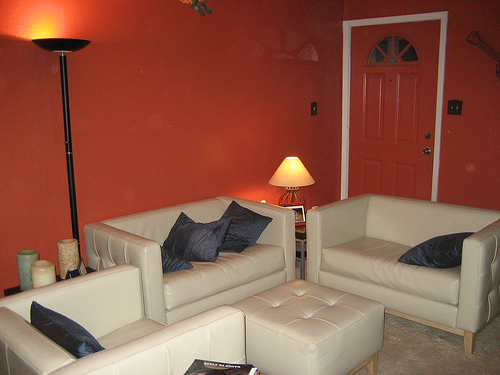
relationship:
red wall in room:
[0, 0, 499, 218] [9, 3, 497, 373]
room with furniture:
[9, 3, 497, 373] [10, 192, 499, 372]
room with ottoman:
[9, 3, 497, 373] [221, 266, 383, 371]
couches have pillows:
[2, 185, 487, 373] [147, 191, 284, 278]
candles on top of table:
[15, 234, 97, 286] [3, 265, 93, 301]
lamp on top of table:
[266, 155, 316, 207] [292, 207, 316, 273]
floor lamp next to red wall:
[33, 36, 92, 273] [0, 0, 499, 218]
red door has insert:
[345, 14, 442, 201] [358, 31, 423, 67]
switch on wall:
[444, 95, 468, 115] [347, 8, 497, 206]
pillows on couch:
[131, 180, 301, 289] [77, 192, 295, 329]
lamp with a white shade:
[266, 155, 316, 207] [269, 151, 319, 189]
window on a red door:
[365, 33, 421, 68] [345, 14, 442, 201]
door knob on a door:
[419, 145, 433, 156] [346, 16, 443, 195]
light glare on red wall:
[11, 10, 68, 37] [118, 29, 263, 157]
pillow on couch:
[398, 228, 474, 268] [303, 191, 484, 342]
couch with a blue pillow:
[305, 192, 485, 309] [398, 227, 468, 267]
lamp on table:
[266, 155, 316, 207] [292, 218, 311, 274]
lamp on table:
[266, 155, 316, 207] [296, 223, 308, 277]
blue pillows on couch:
[149, 199, 272, 274] [82, 194, 298, 310]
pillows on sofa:
[131, 180, 301, 289] [64, 177, 301, 289]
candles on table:
[77, 234, 139, 304] [42, 215, 179, 361]